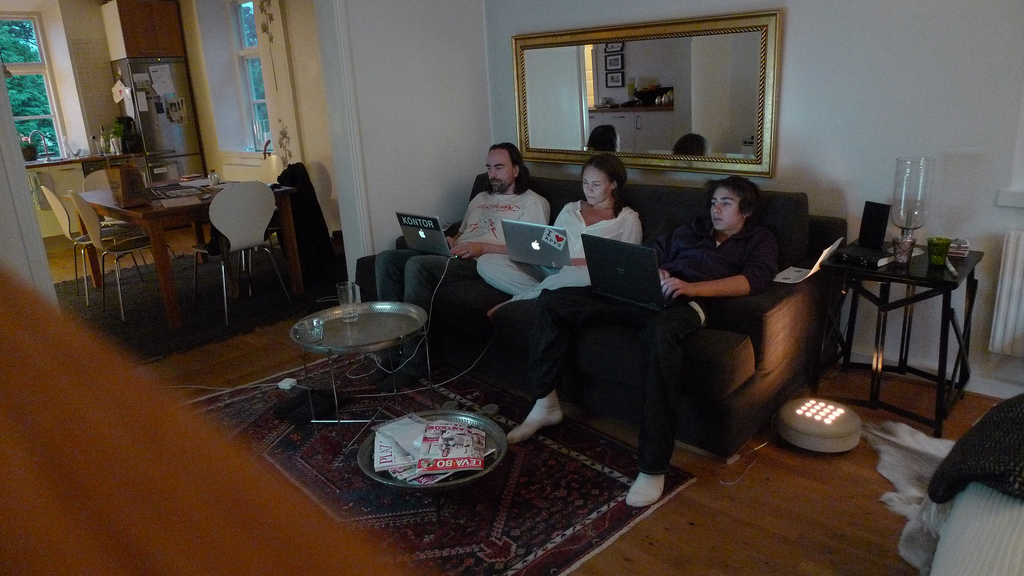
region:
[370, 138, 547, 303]
A man sitting on a couch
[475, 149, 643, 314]
A woman sitting on a couch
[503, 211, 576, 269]
A silver laptop on her lap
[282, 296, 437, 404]
A round silver table on the floor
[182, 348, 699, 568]
A rug on the floor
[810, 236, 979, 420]
A table in a room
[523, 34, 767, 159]
A mirror in a frame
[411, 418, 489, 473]
A magazine laying on a table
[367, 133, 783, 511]
three people sitting on a couch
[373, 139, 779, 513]
three people using laptops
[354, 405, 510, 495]
metal tray of magazines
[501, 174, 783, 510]
teenager wearing black pants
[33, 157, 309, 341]
white metal chairs around wood table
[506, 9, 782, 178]
long wall mirror with gold framing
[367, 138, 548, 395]
man wearing white shirt and blue jeans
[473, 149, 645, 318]
woman sitting cross legged on a couch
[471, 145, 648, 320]
woman wearing white clothing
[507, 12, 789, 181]
A frame on a wall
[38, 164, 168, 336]
Chairs on the floor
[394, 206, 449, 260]
A laptop on a man's lap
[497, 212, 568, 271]
A silver laptop on a woman's lap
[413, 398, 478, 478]
A magazine on a table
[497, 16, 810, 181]
mirror hanging on the wall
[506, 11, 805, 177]
mirror is in a gold frame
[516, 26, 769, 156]
reflection in the mirror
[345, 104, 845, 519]
three people sitting on the couch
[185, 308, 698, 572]
dark area rug on the floor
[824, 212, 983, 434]
small table beside the couch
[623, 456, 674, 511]
white sock on the foot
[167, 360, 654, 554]
a rug on the floor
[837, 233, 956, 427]
a black end table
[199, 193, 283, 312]
a white chair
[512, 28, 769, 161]
a mirror on the wall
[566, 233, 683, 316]
a laptop computer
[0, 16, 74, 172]
a window in the room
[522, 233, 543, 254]
Logo on a laptop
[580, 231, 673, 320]
Laptop on a person's lap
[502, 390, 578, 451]
White socks on a man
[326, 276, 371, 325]
Glass on a table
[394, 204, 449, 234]
Sticker on a laptop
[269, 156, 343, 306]
Jacket on a chair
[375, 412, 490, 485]
Magazines on the floor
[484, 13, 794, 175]
Mirror on the wall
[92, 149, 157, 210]
Paper bag on the table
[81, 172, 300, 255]
Table made of wood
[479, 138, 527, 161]
the hair of a man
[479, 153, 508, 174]
the eyes of a man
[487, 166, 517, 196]
the beard of a man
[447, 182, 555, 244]
the shirt of a man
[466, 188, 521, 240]
the torso of a man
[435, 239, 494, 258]
the arm of a man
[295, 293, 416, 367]
a table that is bmetal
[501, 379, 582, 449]
a foot that has a sock on it